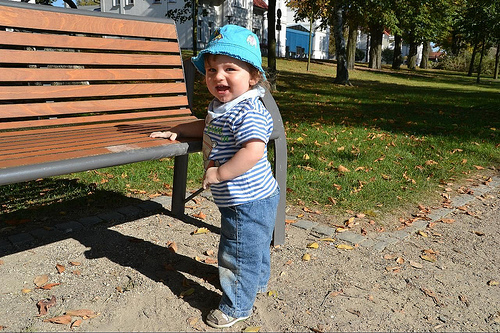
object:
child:
[147, 23, 285, 330]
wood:
[0, 80, 189, 103]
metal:
[0, 0, 289, 246]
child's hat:
[190, 23, 269, 81]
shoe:
[194, 76, 203, 307]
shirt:
[198, 85, 283, 209]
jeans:
[210, 186, 284, 320]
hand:
[150, 130, 180, 141]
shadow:
[1, 116, 225, 325]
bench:
[0, 0, 289, 247]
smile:
[214, 84, 230, 94]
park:
[1, 0, 500, 333]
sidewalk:
[0, 172, 500, 333]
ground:
[0, 53, 500, 333]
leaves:
[482, 278, 500, 289]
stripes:
[211, 199, 252, 206]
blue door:
[286, 27, 315, 59]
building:
[285, 17, 334, 63]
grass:
[420, 188, 427, 193]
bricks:
[1, 236, 15, 254]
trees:
[486, 0, 499, 86]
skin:
[231, 68, 252, 95]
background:
[67, 0, 499, 144]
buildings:
[423, 37, 442, 67]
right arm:
[175, 119, 207, 136]